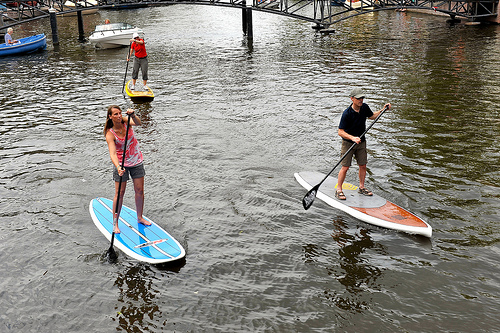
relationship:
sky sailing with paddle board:
[201, 71, 263, 100] [294, 170, 433, 239]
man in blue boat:
[1, 24, 21, 49] [1, 23, 51, 60]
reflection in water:
[114, 258, 155, 328] [1, 2, 497, 332]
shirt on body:
[128, 44, 148, 55] [316, 87, 401, 207]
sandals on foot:
[333, 182, 375, 198] [333, 188, 348, 201]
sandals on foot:
[333, 182, 375, 198] [355, 179, 372, 196]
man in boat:
[4, 27, 19, 46] [89, 189, 188, 267]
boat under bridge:
[85, 22, 146, 50] [36, 2, 459, 53]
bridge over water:
[4, 0, 495, 31] [1, 2, 497, 332]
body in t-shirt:
[334, 88, 391, 201] [336, 102, 373, 138]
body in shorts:
[334, 88, 391, 201] [336, 135, 368, 167]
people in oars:
[126, 32, 148, 90] [122, 41, 132, 93]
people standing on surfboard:
[58, 25, 464, 273] [287, 158, 454, 258]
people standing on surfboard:
[58, 25, 464, 273] [79, 190, 186, 265]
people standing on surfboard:
[58, 25, 464, 273] [112, 65, 169, 117]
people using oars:
[110, 28, 388, 208] [119, 37, 134, 90]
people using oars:
[110, 28, 388, 208] [298, 99, 400, 211]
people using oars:
[110, 28, 388, 208] [100, 112, 135, 260]